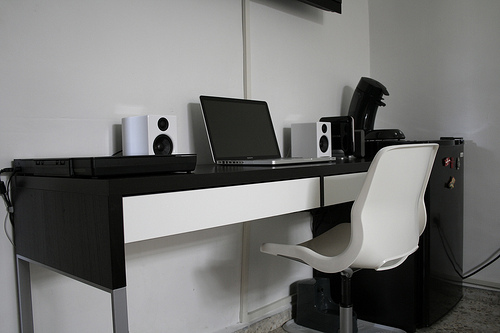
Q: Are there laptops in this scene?
A: Yes, there is a laptop.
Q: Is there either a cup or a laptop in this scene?
A: Yes, there is a laptop.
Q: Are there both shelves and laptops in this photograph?
A: No, there is a laptop but no shelves.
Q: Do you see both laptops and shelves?
A: No, there is a laptop but no shelves.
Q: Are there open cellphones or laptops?
A: Yes, there is an open laptop.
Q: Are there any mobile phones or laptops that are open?
A: Yes, the laptop is open.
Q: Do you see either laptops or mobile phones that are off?
A: Yes, the laptop is off.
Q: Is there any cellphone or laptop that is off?
A: Yes, the laptop is off.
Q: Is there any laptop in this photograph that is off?
A: Yes, there is a laptop that is off.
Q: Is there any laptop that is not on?
A: Yes, there is a laptop that is off.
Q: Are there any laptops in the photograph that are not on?
A: Yes, there is a laptop that is off.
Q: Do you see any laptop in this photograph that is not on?
A: Yes, there is a laptop that is off .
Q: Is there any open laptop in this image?
A: Yes, there is an open laptop.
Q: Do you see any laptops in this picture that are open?
A: Yes, there is a laptop that is open.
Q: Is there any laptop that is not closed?
A: Yes, there is a open laptop.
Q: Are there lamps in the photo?
A: No, there are no lamps.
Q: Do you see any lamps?
A: No, there are no lamps.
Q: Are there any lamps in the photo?
A: No, there are no lamps.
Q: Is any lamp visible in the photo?
A: No, there are no lamps.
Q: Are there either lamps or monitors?
A: No, there are no lamps or monitors.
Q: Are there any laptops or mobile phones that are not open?
A: No, there is a laptop but it is open.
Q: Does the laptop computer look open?
A: Yes, the laptop computer is open.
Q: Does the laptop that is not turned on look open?
A: Yes, the laptop computer is open.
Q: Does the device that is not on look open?
A: Yes, the laptop computer is open.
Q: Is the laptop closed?
A: No, the laptop is open.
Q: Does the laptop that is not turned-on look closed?
A: No, the laptop is open.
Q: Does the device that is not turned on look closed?
A: No, the laptop is open.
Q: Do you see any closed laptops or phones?
A: No, there is a laptop but it is open.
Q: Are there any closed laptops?
A: No, there is a laptop but it is open.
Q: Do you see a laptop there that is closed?
A: No, there is a laptop but it is open.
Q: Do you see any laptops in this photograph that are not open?
A: No, there is a laptop but it is open.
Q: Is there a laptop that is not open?
A: No, there is a laptop but it is open.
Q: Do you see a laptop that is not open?
A: No, there is a laptop but it is open.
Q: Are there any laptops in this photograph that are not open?
A: No, there is a laptop but it is open.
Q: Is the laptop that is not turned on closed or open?
A: The laptop is open.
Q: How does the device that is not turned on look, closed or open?
A: The laptop is open.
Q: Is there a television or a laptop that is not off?
A: No, there is a laptop but it is off.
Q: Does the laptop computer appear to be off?
A: Yes, the laptop computer is off.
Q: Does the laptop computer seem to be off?
A: Yes, the laptop computer is off.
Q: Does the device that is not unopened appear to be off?
A: Yes, the laptop computer is off.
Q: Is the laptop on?
A: No, the laptop is off.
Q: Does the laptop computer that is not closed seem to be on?
A: No, the laptop is off.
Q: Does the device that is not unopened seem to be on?
A: No, the laptop is off.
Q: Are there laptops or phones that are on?
A: No, there is a laptop but it is off.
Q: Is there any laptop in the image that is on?
A: No, there is a laptop but it is off.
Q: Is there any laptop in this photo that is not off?
A: No, there is a laptop but it is off.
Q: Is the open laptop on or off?
A: The laptop is off.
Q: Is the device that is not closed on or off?
A: The laptop is off.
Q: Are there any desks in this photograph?
A: Yes, there is a desk.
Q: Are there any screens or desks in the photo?
A: Yes, there is a desk.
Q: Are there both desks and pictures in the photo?
A: No, there is a desk but no pictures.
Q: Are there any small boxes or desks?
A: Yes, there is a small desk.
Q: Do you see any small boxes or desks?
A: Yes, there is a small desk.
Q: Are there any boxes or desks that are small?
A: Yes, the desk is small.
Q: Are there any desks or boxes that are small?
A: Yes, the desk is small.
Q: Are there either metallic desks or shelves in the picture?
A: Yes, there is a metal desk.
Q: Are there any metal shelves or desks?
A: Yes, there is a metal desk.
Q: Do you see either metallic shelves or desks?
A: Yes, there is a metal desk.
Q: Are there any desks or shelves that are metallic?
A: Yes, the desk is metallic.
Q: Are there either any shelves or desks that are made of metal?
A: Yes, the desk is made of metal.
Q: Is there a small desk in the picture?
A: Yes, there is a small desk.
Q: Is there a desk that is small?
A: Yes, there is a desk that is small.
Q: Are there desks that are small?
A: Yes, there is a desk that is small.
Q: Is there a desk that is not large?
A: Yes, there is a small desk.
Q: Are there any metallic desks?
A: Yes, there is a metal desk.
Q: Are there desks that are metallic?
A: Yes, there is a desk that is metallic.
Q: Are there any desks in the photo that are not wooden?
A: Yes, there is a metallic desk.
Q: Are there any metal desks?
A: Yes, there is a desk that is made of metal.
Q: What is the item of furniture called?
A: The piece of furniture is a desk.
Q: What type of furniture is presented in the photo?
A: The furniture is a desk.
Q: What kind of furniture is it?
A: The piece of furniture is a desk.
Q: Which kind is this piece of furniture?
A: This is a desk.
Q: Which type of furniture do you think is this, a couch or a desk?
A: This is a desk.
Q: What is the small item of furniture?
A: The piece of furniture is a desk.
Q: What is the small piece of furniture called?
A: The piece of furniture is a desk.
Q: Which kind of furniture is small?
A: The furniture is a desk.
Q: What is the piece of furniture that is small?
A: The piece of furniture is a desk.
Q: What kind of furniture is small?
A: The furniture is a desk.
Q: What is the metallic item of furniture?
A: The piece of furniture is a desk.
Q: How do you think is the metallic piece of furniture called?
A: The piece of furniture is a desk.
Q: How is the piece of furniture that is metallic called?
A: The piece of furniture is a desk.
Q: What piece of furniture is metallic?
A: The piece of furniture is a desk.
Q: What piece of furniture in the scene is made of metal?
A: The piece of furniture is a desk.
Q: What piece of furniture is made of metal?
A: The piece of furniture is a desk.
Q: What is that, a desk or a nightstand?
A: That is a desk.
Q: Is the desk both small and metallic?
A: Yes, the desk is small and metallic.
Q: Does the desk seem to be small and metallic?
A: Yes, the desk is small and metallic.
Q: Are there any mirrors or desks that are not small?
A: No, there is a desk but it is small.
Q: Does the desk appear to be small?
A: Yes, the desk is small.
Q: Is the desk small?
A: Yes, the desk is small.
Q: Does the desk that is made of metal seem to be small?
A: Yes, the desk is small.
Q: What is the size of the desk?
A: The desk is small.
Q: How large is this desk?
A: The desk is small.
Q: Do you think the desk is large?
A: No, the desk is small.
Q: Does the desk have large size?
A: No, the desk is small.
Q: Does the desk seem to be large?
A: No, the desk is small.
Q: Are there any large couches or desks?
A: No, there is a desk but it is small.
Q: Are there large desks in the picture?
A: No, there is a desk but it is small.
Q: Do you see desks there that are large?
A: No, there is a desk but it is small.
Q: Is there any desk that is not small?
A: No, there is a desk but it is small.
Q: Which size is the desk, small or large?
A: The desk is small.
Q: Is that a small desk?
A: Yes, that is a small desk.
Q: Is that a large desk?
A: No, that is a small desk.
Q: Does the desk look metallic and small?
A: Yes, the desk is metallic and small.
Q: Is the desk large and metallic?
A: No, the desk is metallic but small.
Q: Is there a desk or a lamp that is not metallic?
A: No, there is a desk but it is metallic.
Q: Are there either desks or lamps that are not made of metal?
A: No, there is a desk but it is made of metal.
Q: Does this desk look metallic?
A: Yes, the desk is metallic.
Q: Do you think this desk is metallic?
A: Yes, the desk is metallic.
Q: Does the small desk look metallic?
A: Yes, the desk is metallic.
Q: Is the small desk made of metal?
A: Yes, the desk is made of metal.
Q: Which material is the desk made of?
A: The desk is made of metal.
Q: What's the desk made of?
A: The desk is made of metal.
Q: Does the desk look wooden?
A: No, the desk is metallic.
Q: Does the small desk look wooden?
A: No, the desk is metallic.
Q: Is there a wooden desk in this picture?
A: No, there is a desk but it is metallic.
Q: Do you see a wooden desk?
A: No, there is a desk but it is metallic.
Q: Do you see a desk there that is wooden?
A: No, there is a desk but it is metallic.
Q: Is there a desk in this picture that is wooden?
A: No, there is a desk but it is metallic.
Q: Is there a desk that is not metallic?
A: No, there is a desk but it is metallic.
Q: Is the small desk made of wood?
A: No, the desk is made of metal.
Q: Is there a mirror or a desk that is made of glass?
A: No, there is a desk but it is made of metal.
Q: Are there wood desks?
A: No, there is a desk but it is made of metal.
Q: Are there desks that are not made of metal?
A: No, there is a desk but it is made of metal.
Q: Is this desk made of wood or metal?
A: The desk is made of metal.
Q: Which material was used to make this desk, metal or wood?
A: The desk is made of metal.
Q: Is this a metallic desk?
A: Yes, this is a metallic desk.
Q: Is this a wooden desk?
A: No, this is a metallic desk.